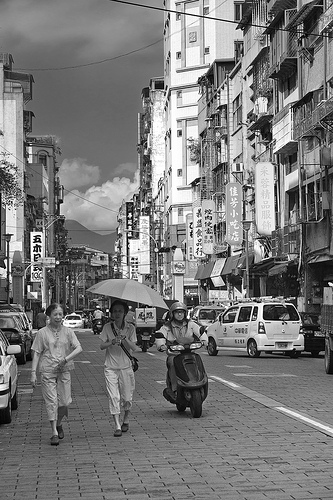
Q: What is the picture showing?
A: It is showing a road.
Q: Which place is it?
A: It is a road.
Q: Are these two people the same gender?
A: Yes, all the people are female.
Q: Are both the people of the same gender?
A: Yes, all the people are female.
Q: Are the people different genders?
A: No, all the people are female.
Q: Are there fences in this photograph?
A: No, there are no fences.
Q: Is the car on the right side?
A: Yes, the car is on the right of the image.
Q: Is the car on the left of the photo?
A: No, the car is on the right of the image.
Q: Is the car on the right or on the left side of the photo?
A: The car is on the right of the image.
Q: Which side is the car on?
A: The car is on the right of the image.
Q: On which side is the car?
A: The car is on the right of the image.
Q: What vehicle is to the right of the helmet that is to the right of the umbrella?
A: The vehicle is a car.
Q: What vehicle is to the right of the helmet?
A: The vehicle is a car.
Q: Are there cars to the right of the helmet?
A: Yes, there is a car to the right of the helmet.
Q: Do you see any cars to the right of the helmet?
A: Yes, there is a car to the right of the helmet.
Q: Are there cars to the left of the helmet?
A: No, the car is to the right of the helmet.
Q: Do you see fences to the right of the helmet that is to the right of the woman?
A: No, there is a car to the right of the helmet.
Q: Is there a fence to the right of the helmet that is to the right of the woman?
A: No, there is a car to the right of the helmet.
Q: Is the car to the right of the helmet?
A: Yes, the car is to the right of the helmet.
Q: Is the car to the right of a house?
A: No, the car is to the right of the helmet.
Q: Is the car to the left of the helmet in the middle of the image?
A: No, the car is to the right of the helmet.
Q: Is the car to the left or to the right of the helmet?
A: The car is to the right of the helmet.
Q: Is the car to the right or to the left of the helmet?
A: The car is to the right of the helmet.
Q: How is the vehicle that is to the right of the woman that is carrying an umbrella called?
A: The vehicle is a car.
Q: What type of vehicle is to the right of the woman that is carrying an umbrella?
A: The vehicle is a car.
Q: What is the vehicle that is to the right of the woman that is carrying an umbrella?
A: The vehicle is a car.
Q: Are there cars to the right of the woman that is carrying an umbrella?
A: Yes, there is a car to the right of the woman.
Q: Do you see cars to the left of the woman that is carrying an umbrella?
A: No, the car is to the right of the woman.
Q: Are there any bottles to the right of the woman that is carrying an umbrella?
A: No, there is a car to the right of the woman.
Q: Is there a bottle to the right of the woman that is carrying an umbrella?
A: No, there is a car to the right of the woman.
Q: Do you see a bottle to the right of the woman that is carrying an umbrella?
A: No, there is a car to the right of the woman.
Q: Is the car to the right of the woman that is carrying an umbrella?
A: Yes, the car is to the right of the woman.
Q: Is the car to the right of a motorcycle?
A: No, the car is to the right of the woman.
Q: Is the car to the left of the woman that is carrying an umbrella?
A: No, the car is to the right of the woman.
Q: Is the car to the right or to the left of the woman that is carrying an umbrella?
A: The car is to the right of the woman.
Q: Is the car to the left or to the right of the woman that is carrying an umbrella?
A: The car is to the right of the woman.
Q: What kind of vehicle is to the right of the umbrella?
A: The vehicle is a car.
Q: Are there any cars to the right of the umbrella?
A: Yes, there is a car to the right of the umbrella.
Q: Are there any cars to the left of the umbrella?
A: No, the car is to the right of the umbrella.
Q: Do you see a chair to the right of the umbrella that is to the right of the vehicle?
A: No, there is a car to the right of the umbrella.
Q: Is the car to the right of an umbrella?
A: Yes, the car is to the right of an umbrella.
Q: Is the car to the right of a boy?
A: No, the car is to the right of an umbrella.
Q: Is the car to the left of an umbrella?
A: No, the car is to the right of an umbrella.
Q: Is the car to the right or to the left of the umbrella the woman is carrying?
A: The car is to the right of the umbrella.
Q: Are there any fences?
A: No, there are no fences.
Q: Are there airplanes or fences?
A: No, there are no fences or airplanes.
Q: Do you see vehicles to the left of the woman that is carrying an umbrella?
A: Yes, there is a vehicle to the left of the woman.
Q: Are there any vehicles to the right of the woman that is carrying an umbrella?
A: No, the vehicle is to the left of the woman.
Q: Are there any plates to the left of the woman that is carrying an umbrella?
A: No, there is a vehicle to the left of the woman.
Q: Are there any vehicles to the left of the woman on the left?
A: Yes, there is a vehicle to the left of the woman.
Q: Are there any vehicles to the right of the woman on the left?
A: No, the vehicle is to the left of the woman.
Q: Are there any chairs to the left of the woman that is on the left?
A: No, there is a vehicle to the left of the woman.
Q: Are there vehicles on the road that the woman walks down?
A: Yes, there is a vehicle on the road.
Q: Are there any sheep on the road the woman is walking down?
A: No, there is a vehicle on the road.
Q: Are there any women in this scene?
A: Yes, there is a woman.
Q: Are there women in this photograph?
A: Yes, there is a woman.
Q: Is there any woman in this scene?
A: Yes, there is a woman.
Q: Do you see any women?
A: Yes, there is a woman.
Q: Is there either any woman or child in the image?
A: Yes, there is a woman.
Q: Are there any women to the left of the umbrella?
A: Yes, there is a woman to the left of the umbrella.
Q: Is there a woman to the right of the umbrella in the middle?
A: No, the woman is to the left of the umbrella.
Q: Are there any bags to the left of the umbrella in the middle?
A: No, there is a woman to the left of the umbrella.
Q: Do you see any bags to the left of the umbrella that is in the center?
A: No, there is a woman to the left of the umbrella.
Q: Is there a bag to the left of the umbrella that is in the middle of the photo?
A: No, there is a woman to the left of the umbrella.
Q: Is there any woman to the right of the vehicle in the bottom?
A: Yes, there is a woman to the right of the vehicle.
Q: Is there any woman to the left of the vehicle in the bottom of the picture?
A: No, the woman is to the right of the vehicle.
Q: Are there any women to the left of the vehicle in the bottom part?
A: No, the woman is to the right of the vehicle.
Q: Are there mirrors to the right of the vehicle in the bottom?
A: No, there is a woman to the right of the vehicle.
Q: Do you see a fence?
A: No, there are no fences.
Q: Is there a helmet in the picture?
A: Yes, there is a helmet.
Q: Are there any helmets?
A: Yes, there is a helmet.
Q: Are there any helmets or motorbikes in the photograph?
A: Yes, there is a helmet.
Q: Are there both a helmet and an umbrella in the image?
A: Yes, there are both a helmet and an umbrella.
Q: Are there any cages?
A: No, there are no cages.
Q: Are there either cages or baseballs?
A: No, there are no cages or baseballs.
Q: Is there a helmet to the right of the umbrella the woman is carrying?
A: Yes, there is a helmet to the right of the umbrella.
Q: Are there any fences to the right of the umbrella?
A: No, there is a helmet to the right of the umbrella.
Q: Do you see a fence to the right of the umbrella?
A: No, there is a helmet to the right of the umbrella.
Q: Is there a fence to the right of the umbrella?
A: No, there is a helmet to the right of the umbrella.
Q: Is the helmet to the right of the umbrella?
A: Yes, the helmet is to the right of the umbrella.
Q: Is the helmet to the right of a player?
A: No, the helmet is to the right of the umbrella.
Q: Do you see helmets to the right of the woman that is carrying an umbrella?
A: Yes, there is a helmet to the right of the woman.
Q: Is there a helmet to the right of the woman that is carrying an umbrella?
A: Yes, there is a helmet to the right of the woman.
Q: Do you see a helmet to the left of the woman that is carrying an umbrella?
A: No, the helmet is to the right of the woman.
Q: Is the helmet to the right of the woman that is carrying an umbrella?
A: Yes, the helmet is to the right of the woman.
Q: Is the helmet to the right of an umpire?
A: No, the helmet is to the right of the woman.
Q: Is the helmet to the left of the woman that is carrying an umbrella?
A: No, the helmet is to the right of the woman.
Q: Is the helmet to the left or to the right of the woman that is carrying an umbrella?
A: The helmet is to the right of the woman.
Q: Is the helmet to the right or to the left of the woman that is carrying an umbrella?
A: The helmet is to the right of the woman.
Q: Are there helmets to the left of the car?
A: Yes, there is a helmet to the left of the car.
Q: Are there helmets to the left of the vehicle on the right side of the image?
A: Yes, there is a helmet to the left of the car.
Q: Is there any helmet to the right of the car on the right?
A: No, the helmet is to the left of the car.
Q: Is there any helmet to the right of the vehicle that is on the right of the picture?
A: No, the helmet is to the left of the car.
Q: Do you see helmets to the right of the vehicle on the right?
A: No, the helmet is to the left of the car.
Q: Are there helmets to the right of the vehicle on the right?
A: No, the helmet is to the left of the car.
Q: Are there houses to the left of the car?
A: No, there is a helmet to the left of the car.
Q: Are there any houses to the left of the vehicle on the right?
A: No, there is a helmet to the left of the car.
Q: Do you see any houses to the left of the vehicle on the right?
A: No, there is a helmet to the left of the car.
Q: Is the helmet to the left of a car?
A: Yes, the helmet is to the left of a car.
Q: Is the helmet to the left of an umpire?
A: No, the helmet is to the left of a car.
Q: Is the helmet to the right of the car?
A: No, the helmet is to the left of the car.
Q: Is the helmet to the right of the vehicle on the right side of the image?
A: No, the helmet is to the left of the car.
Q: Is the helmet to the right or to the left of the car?
A: The helmet is to the left of the car.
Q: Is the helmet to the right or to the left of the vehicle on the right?
A: The helmet is to the left of the car.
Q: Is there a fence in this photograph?
A: No, there are no fences.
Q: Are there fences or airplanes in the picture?
A: No, there are no fences or airplanes.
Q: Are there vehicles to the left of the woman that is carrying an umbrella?
A: Yes, there is a vehicle to the left of the woman.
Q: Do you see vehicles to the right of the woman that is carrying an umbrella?
A: No, the vehicle is to the left of the woman.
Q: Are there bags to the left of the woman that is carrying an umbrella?
A: No, there is a vehicle to the left of the woman.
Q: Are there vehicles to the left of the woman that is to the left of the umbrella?
A: Yes, there is a vehicle to the left of the woman.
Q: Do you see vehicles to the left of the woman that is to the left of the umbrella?
A: Yes, there is a vehicle to the left of the woman.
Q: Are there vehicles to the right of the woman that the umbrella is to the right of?
A: No, the vehicle is to the left of the woman.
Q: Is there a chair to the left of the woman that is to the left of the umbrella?
A: No, there is a vehicle to the left of the woman.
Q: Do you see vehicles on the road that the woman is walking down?
A: Yes, there is a vehicle on the road.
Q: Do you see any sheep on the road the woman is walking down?
A: No, there is a vehicle on the road.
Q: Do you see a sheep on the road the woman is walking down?
A: No, there is a vehicle on the road.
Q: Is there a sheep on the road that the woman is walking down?
A: No, there is a vehicle on the road.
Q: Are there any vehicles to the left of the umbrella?
A: Yes, there is a vehicle to the left of the umbrella.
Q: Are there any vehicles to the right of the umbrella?
A: No, the vehicle is to the left of the umbrella.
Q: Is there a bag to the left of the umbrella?
A: No, there is a vehicle to the left of the umbrella.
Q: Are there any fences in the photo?
A: No, there are no fences.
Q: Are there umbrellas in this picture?
A: Yes, there is an umbrella.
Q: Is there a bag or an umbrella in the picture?
A: Yes, there is an umbrella.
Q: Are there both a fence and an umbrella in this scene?
A: No, there is an umbrella but no fences.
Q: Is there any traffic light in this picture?
A: No, there are no traffic lights.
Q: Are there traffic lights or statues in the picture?
A: No, there are no traffic lights or statues.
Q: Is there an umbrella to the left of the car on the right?
A: Yes, there is an umbrella to the left of the car.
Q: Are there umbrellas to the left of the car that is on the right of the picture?
A: Yes, there is an umbrella to the left of the car.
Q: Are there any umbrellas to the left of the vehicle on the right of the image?
A: Yes, there is an umbrella to the left of the car.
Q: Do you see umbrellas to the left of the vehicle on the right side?
A: Yes, there is an umbrella to the left of the car.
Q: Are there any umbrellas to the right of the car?
A: No, the umbrella is to the left of the car.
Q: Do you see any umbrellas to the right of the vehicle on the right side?
A: No, the umbrella is to the left of the car.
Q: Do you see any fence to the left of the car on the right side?
A: No, there is an umbrella to the left of the car.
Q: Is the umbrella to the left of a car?
A: Yes, the umbrella is to the left of a car.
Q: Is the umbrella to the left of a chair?
A: No, the umbrella is to the left of a car.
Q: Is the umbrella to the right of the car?
A: No, the umbrella is to the left of the car.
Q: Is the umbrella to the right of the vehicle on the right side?
A: No, the umbrella is to the left of the car.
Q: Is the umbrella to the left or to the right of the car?
A: The umbrella is to the left of the car.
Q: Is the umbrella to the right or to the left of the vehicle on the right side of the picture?
A: The umbrella is to the left of the car.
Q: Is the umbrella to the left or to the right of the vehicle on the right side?
A: The umbrella is to the left of the car.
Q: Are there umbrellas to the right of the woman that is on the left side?
A: Yes, there is an umbrella to the right of the woman.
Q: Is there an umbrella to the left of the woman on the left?
A: No, the umbrella is to the right of the woman.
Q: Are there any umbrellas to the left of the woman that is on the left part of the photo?
A: No, the umbrella is to the right of the woman.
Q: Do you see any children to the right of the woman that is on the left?
A: No, there is an umbrella to the right of the woman.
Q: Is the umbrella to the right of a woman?
A: Yes, the umbrella is to the right of a woman.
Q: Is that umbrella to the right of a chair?
A: No, the umbrella is to the right of a woman.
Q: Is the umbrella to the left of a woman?
A: No, the umbrella is to the right of a woman.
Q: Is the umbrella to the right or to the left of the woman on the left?
A: The umbrella is to the right of the woman.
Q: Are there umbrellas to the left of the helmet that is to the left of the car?
A: Yes, there is an umbrella to the left of the helmet.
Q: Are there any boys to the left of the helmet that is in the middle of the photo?
A: No, there is an umbrella to the left of the helmet.